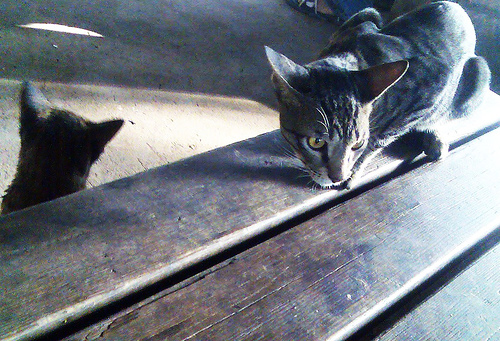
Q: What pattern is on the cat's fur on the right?
A: Stripes.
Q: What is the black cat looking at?
A: Reflection.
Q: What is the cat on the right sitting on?
A: Table.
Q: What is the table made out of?
A: Wood.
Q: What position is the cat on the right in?
A: Crouching.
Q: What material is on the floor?
A: Carpet.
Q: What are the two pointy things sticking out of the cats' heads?
A: Ears.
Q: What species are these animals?
A: Cats.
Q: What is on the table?
A: Wood.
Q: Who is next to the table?
A: A cat.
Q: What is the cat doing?
A: Looking away.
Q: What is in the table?
A: A crack.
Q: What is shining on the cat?
A: Sunlight.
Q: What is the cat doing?
A: Crouching down.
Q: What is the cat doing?
A: Crouching on the bench.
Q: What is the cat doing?
A: Looking away.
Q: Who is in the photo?
A: A cat.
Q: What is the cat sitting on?
A: Bench.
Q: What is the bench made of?
A: Wood.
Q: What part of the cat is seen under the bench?
A: Head.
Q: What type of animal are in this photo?
A: Cats.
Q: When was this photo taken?
A: Daytime.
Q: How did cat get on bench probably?
A: Jumped.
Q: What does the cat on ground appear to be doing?
A: Sitting.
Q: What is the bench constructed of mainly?
A: Wood.